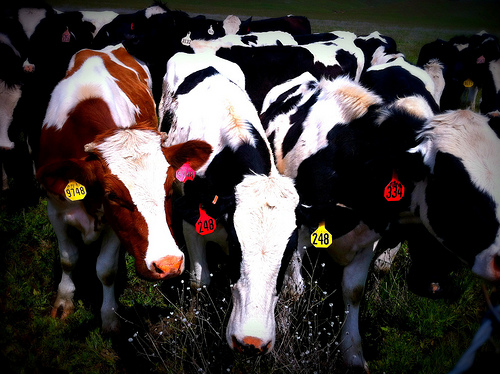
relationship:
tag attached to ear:
[460, 77, 477, 90] [295, 197, 357, 238]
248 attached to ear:
[196, 217, 213, 232] [161, 137, 213, 181]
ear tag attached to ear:
[310, 221, 334, 248] [36, 155, 103, 203]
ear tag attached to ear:
[310, 221, 334, 248] [177, 185, 234, 222]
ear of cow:
[295, 197, 357, 238] [417, 37, 492, 104]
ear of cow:
[161, 137, 213, 181] [261, 68, 498, 371]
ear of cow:
[36, 155, 103, 203] [167, 50, 300, 355]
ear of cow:
[177, 185, 234, 222] [32, 44, 201, 333]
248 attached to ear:
[196, 217, 213, 232] [181, 162, 238, 235]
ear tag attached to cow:
[310, 221, 334, 248] [261, 68, 498, 371]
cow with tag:
[167, 50, 300, 355] [385, 175, 410, 202]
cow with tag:
[265, 66, 433, 372] [195, 205, 217, 235]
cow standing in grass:
[167, 50, 300, 355] [3, 195, 498, 370]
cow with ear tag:
[167, 50, 300, 355] [195, 204, 215, 235]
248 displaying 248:
[196, 217, 213, 232] [196, 217, 213, 232]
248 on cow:
[196, 217, 213, 232] [29, 40, 212, 340]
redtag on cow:
[172, 156, 197, 182] [167, 50, 300, 355]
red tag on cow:
[385, 173, 403, 202] [261, 68, 498, 371]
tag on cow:
[169, 161, 196, 184] [46, 40, 176, 277]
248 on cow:
[196, 217, 213, 232] [157, 53, 347, 353]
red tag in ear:
[385, 169, 409, 201] [373, 147, 435, 198]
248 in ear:
[196, 217, 213, 232] [165, 135, 215, 187]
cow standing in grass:
[167, 50, 300, 355] [371, 286, 451, 363]